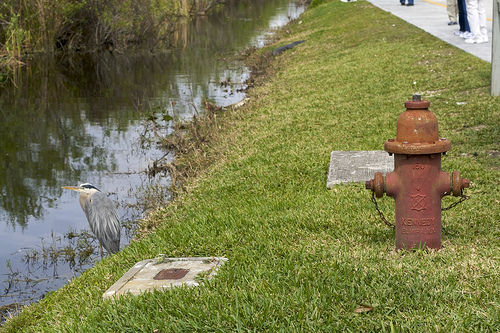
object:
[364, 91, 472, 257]
fire hydrant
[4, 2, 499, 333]
grass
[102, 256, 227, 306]
concrete block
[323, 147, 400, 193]
concrete block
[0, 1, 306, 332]
water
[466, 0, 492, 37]
pants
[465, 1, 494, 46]
person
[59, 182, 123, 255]
bird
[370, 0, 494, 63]
sidewalk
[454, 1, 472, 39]
person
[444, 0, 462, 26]
person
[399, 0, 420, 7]
person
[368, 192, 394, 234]
chain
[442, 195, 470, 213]
chain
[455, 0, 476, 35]
pants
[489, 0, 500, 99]
post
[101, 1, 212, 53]
tree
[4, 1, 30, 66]
plants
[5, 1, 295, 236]
reflections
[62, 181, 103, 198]
head